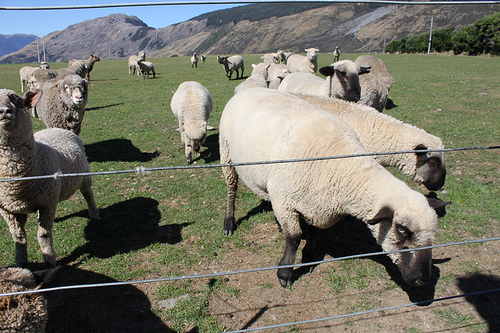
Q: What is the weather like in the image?
A: It is cloudless.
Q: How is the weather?
A: It is cloudless.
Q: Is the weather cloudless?
A: Yes, it is cloudless.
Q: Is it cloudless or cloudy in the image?
A: It is cloudless.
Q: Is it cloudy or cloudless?
A: It is cloudless.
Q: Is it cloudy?
A: No, it is cloudless.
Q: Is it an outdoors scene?
A: Yes, it is outdoors.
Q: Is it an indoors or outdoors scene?
A: It is outdoors.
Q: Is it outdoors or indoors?
A: It is outdoors.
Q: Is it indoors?
A: No, it is outdoors.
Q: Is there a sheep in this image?
A: Yes, there is a sheep.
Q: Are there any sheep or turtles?
A: Yes, there is a sheep.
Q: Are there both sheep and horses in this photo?
A: No, there is a sheep but no horses.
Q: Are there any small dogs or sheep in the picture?
A: Yes, there is a small sheep.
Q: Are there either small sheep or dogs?
A: Yes, there is a small sheep.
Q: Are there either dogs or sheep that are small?
A: Yes, the sheep is small.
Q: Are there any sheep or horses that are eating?
A: Yes, the sheep is eating.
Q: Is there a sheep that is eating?
A: Yes, there is a sheep that is eating.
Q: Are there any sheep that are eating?
A: Yes, there is a sheep that is eating.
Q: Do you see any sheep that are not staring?
A: Yes, there is a sheep that is eating .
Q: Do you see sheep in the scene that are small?
A: Yes, there is a small sheep.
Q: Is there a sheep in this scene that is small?
A: Yes, there is a sheep that is small.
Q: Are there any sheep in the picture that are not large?
A: Yes, there is a small sheep.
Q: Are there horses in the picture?
A: No, there are no horses.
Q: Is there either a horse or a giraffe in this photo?
A: No, there are no horses or giraffes.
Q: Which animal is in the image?
A: The animal is a sheep.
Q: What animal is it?
A: The animal is a sheep.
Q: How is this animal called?
A: This is a sheep.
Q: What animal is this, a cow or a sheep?
A: This is a sheep.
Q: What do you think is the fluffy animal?
A: The animal is a sheep.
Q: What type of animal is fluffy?
A: The animal is a sheep.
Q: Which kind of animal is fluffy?
A: The animal is a sheep.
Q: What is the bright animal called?
A: The animal is a sheep.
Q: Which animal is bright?
A: The animal is a sheep.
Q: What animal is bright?
A: The animal is a sheep.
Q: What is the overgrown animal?
A: The animal is a sheep.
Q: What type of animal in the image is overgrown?
A: The animal is a sheep.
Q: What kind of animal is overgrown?
A: The animal is a sheep.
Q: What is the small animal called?
A: The animal is a sheep.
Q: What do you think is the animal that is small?
A: The animal is a sheep.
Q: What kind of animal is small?
A: The animal is a sheep.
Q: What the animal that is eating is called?
A: The animal is a sheep.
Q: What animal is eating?
A: The animal is a sheep.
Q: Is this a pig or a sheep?
A: This is a sheep.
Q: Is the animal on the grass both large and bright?
A: No, the sheep is bright but small.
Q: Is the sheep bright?
A: Yes, the sheep is bright.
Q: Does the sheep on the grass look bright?
A: Yes, the sheep is bright.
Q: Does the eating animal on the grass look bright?
A: Yes, the sheep is bright.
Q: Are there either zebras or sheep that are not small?
A: No, there is a sheep but it is small.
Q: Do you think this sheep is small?
A: Yes, the sheep is small.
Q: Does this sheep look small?
A: Yes, the sheep is small.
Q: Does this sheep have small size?
A: Yes, the sheep is small.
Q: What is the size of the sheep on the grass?
A: The sheep is small.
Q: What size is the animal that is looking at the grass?
A: The sheep is small.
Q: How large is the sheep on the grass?
A: The sheep is small.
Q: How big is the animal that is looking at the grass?
A: The sheep is small.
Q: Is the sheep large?
A: No, the sheep is small.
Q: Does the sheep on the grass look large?
A: No, the sheep is small.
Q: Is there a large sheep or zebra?
A: No, there is a sheep but it is small.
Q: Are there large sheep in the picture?
A: No, there is a sheep but it is small.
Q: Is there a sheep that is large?
A: No, there is a sheep but it is small.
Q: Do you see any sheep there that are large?
A: No, there is a sheep but it is small.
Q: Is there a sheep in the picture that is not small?
A: No, there is a sheep but it is small.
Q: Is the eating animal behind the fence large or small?
A: The sheep is small.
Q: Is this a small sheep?
A: Yes, this is a small sheep.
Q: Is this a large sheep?
A: No, this is a small sheep.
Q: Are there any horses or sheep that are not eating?
A: No, there is a sheep but it is eating.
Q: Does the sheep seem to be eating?
A: Yes, the sheep is eating.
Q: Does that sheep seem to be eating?
A: Yes, the sheep is eating.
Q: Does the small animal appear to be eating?
A: Yes, the sheep is eating.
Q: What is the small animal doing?
A: The sheep is eating.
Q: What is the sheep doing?
A: The sheep is eating.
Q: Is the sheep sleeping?
A: No, the sheep is eating.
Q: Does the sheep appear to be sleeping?
A: No, the sheep is eating.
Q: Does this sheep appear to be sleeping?
A: No, the sheep is eating.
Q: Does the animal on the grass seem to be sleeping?
A: No, the sheep is eating.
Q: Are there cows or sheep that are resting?
A: No, there is a sheep but it is eating.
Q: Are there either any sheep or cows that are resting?
A: No, there is a sheep but it is eating.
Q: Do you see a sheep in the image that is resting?
A: No, there is a sheep but it is eating.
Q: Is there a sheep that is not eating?
A: No, there is a sheep but it is eating.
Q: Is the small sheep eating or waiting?
A: The sheep is eating.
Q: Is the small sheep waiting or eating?
A: The sheep is eating.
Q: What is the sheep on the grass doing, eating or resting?
A: The sheep is eating.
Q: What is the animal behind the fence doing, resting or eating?
A: The sheep is eating.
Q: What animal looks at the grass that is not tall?
A: The sheep looks at the grass.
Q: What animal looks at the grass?
A: The sheep looks at the grass.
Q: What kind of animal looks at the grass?
A: The animal is a sheep.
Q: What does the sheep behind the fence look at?
A: The sheep looks at the grass.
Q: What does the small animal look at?
A: The sheep looks at the grass.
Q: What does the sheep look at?
A: The sheep looks at the grass.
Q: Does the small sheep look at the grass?
A: Yes, the sheep looks at the grass.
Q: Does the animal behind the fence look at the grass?
A: Yes, the sheep looks at the grass.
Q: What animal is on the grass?
A: The sheep is on the grass.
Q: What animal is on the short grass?
A: The animal is a sheep.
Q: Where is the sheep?
A: The sheep is on the grass.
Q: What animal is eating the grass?
A: The sheep is eating the grass.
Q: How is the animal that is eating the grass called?
A: The animal is a sheep.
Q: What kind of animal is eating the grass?
A: The animal is a sheep.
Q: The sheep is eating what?
A: The sheep is eating grass.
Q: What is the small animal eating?
A: The sheep is eating grass.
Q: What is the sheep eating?
A: The sheep is eating grass.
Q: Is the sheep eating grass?
A: Yes, the sheep is eating grass.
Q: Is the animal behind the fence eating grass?
A: Yes, the sheep is eating grass.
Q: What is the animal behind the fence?
A: The animal is a sheep.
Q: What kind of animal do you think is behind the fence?
A: The animal is a sheep.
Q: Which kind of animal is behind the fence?
A: The animal is a sheep.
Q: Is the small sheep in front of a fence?
A: No, the sheep is behind a fence.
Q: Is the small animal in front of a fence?
A: No, the sheep is behind a fence.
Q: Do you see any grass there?
A: Yes, there is grass.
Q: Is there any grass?
A: Yes, there is grass.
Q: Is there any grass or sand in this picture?
A: Yes, there is grass.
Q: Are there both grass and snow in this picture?
A: No, there is grass but no snow.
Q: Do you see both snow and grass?
A: No, there is grass but no snow.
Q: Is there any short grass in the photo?
A: Yes, there is short grass.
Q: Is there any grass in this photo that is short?
A: Yes, there is grass that is short.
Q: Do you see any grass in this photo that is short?
A: Yes, there is grass that is short.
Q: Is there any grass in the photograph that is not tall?
A: Yes, there is short grass.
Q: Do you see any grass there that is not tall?
A: Yes, there is short grass.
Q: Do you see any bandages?
A: No, there are no bandages.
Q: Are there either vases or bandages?
A: No, there are no bandages or vases.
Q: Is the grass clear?
A: Yes, the grass is clear.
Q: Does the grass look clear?
A: Yes, the grass is clear.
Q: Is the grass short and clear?
A: Yes, the grass is short and clear.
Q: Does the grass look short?
A: Yes, the grass is short.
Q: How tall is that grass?
A: The grass is short.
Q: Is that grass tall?
A: No, the grass is short.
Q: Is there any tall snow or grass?
A: No, there is grass but it is short.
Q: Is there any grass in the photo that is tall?
A: No, there is grass but it is short.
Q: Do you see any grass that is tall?
A: No, there is grass but it is short.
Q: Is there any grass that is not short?
A: No, there is grass but it is short.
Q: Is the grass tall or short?
A: The grass is short.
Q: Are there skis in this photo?
A: No, there are no skis.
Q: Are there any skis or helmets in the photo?
A: No, there are no skis or helmets.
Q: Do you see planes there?
A: No, there are no planes.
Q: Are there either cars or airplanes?
A: No, there are no airplanes or cars.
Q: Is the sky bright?
A: Yes, the sky is bright.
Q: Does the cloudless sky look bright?
A: Yes, the sky is bright.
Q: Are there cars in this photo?
A: No, there are no cars.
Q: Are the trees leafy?
A: Yes, the trees are leafy.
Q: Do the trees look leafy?
A: Yes, the trees are leafy.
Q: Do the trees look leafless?
A: No, the trees are leafy.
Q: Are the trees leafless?
A: No, the trees are leafy.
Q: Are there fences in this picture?
A: Yes, there is a fence.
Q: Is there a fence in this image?
A: Yes, there is a fence.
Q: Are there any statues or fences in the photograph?
A: Yes, there is a fence.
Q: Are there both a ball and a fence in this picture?
A: No, there is a fence but no balls.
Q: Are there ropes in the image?
A: No, there are no ropes.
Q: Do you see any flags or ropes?
A: No, there are no ropes or flags.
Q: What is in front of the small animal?
A: The fence is in front of the sheep.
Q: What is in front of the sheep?
A: The fence is in front of the sheep.